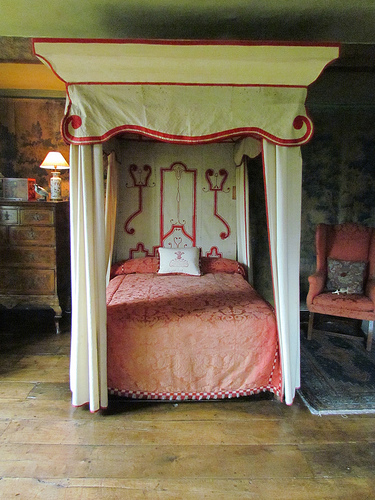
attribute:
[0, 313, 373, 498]
floor — wood, brown, hardwood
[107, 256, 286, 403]
blanket — red, pink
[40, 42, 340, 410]
bed — made, four-poster, antique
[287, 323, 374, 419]
rug — ornamental, turkish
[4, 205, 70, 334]
dresser — wood, brown, antique, clawfoot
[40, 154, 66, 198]
lamp — ceramic, antique, lit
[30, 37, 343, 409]
canopy — white, red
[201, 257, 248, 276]
pillow — red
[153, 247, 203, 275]
pillow — white, decorative, dainty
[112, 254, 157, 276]
pillow — red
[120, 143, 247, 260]
decoration — red, white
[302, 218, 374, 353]
chair — pink, victorian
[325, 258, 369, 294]
pillow — decorative, grey, brown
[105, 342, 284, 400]
fringe — checkered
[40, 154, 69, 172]
shade — light